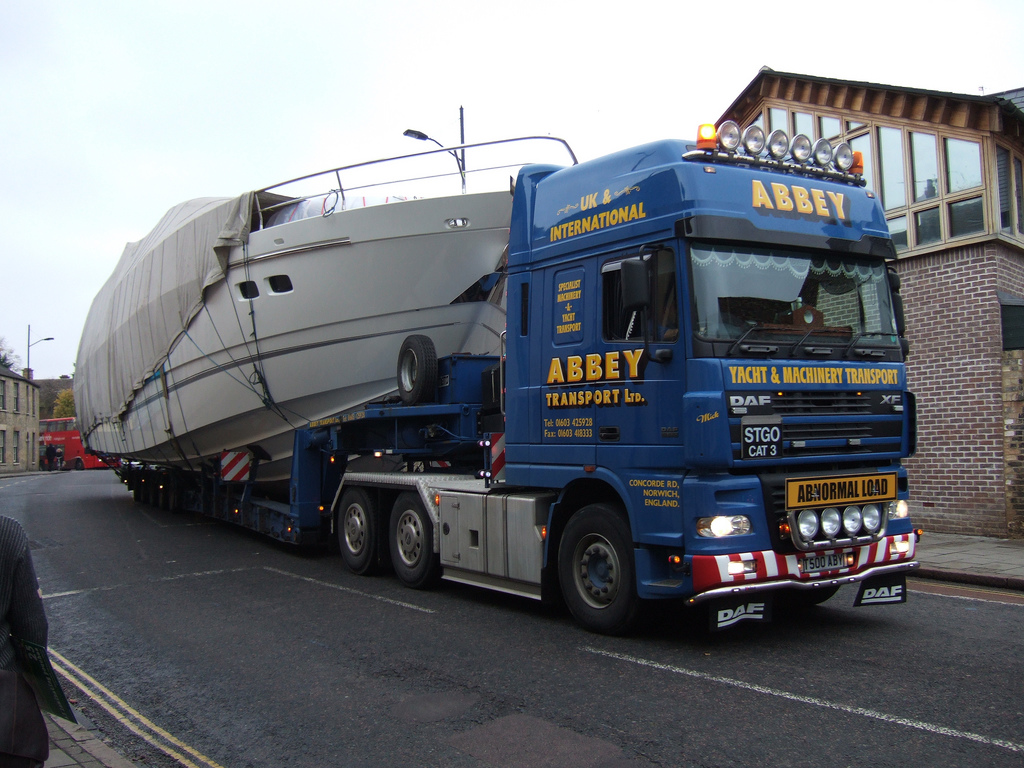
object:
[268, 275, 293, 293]
window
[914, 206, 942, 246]
window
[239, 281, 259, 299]
window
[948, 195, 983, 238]
window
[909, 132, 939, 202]
window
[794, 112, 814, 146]
window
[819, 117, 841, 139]
window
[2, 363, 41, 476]
building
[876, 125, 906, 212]
window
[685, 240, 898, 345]
window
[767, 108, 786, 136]
window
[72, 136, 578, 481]
equipment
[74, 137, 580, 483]
boat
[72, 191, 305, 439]
canvas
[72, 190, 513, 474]
cabin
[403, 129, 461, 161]
street light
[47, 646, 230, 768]
double line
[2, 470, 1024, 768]
road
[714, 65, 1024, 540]
brick building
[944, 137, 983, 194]
window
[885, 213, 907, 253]
window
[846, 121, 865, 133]
window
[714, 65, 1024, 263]
second floor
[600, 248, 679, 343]
window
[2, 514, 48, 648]
arm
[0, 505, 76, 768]
person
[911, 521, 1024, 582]
sidewalk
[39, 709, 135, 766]
sidewalk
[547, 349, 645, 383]
name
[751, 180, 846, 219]
name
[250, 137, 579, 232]
railing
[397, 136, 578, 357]
boat's bow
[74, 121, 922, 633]
truck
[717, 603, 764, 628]
sign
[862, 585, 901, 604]
sign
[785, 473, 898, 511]
abnormal load